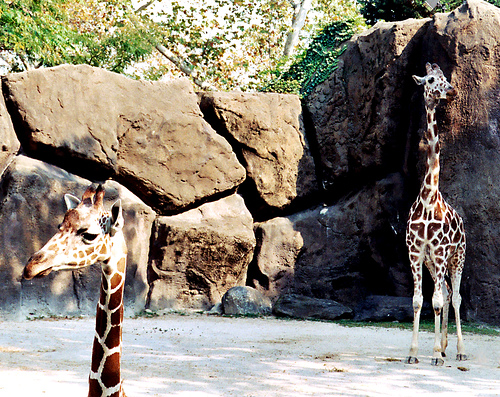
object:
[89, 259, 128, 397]
neck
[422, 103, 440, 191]
neck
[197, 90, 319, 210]
big/brown stone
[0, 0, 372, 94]
trees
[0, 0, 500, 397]
enclosure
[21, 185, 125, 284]
head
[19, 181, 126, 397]
giraffe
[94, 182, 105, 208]
horns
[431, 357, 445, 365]
foot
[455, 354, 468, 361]
foot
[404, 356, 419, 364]
foot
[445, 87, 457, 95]
snout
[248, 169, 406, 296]
stone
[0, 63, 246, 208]
stone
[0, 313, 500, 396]
ground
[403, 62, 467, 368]
giraffe